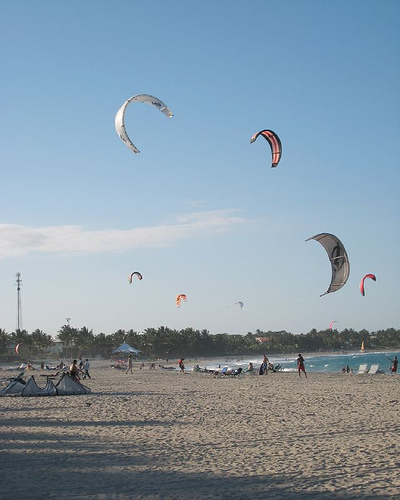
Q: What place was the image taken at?
A: It was taken at the beach.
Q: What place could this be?
A: It is a beach.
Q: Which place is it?
A: It is a beach.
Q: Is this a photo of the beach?
A: Yes, it is showing the beach.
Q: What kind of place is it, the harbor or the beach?
A: It is the beach.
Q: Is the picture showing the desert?
A: No, the picture is showing the beach.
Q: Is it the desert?
A: No, it is the beach.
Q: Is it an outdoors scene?
A: Yes, it is outdoors.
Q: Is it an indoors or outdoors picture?
A: It is outdoors.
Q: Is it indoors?
A: No, it is outdoors.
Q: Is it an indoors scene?
A: No, it is outdoors.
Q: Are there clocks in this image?
A: No, there are no clocks.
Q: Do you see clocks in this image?
A: No, there are no clocks.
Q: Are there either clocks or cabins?
A: No, there are no clocks or cabins.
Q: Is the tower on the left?
A: Yes, the tower is on the left of the image.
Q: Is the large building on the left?
A: Yes, the tower is on the left of the image.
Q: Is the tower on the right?
A: No, the tower is on the left of the image.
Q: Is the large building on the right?
A: No, the tower is on the left of the image.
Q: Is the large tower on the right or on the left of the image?
A: The tower is on the left of the image.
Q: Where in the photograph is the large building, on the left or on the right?
A: The tower is on the left of the image.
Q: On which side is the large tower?
A: The tower is on the left of the image.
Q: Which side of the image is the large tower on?
A: The tower is on the left of the image.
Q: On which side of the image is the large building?
A: The tower is on the left of the image.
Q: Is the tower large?
A: Yes, the tower is large.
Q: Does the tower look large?
A: Yes, the tower is large.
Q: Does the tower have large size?
A: Yes, the tower is large.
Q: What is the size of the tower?
A: The tower is large.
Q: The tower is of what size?
A: The tower is large.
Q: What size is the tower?
A: The tower is large.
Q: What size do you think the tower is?
A: The tower is large.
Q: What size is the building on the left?
A: The tower is large.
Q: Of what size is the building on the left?
A: The tower is large.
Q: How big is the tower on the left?
A: The tower is large.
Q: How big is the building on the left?
A: The tower is large.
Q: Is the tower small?
A: No, the tower is large.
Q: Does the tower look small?
A: No, the tower is large.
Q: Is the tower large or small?
A: The tower is large.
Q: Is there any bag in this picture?
A: No, there are no bags.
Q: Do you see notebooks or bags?
A: No, there are no bags or notebooks.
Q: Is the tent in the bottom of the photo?
A: Yes, the tent is in the bottom of the image.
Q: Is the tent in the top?
A: No, the tent is in the bottom of the image.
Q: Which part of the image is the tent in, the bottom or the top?
A: The tent is in the bottom of the image.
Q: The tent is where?
A: The tent is on the beach.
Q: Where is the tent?
A: The tent is on the beach.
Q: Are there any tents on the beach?
A: Yes, there is a tent on the beach.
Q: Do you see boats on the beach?
A: No, there is a tent on the beach.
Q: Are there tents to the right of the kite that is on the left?
A: Yes, there is a tent to the right of the kite.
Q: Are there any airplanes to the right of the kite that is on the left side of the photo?
A: No, there is a tent to the right of the kite.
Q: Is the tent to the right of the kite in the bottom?
A: Yes, the tent is to the right of the kite.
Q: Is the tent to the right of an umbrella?
A: No, the tent is to the right of the kite.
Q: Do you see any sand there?
A: Yes, there is sand.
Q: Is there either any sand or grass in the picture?
A: Yes, there is sand.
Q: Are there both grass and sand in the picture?
A: No, there is sand but no grass.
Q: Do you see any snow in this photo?
A: No, there is no snow.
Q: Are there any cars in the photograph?
A: No, there are no cars.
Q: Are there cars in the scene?
A: No, there are no cars.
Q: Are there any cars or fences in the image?
A: No, there are no cars or fences.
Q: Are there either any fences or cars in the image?
A: No, there are no cars or fences.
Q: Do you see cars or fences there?
A: No, there are no cars or fences.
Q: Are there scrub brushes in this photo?
A: No, there are no scrub brushes.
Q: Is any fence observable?
A: No, there are no fences.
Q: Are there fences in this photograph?
A: No, there are no fences.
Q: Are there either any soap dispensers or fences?
A: No, there are no fences or soap dispensers.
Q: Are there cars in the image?
A: No, there are no cars.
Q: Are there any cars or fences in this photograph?
A: No, there are no cars or fences.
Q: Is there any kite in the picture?
A: Yes, there is a kite.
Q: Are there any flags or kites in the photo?
A: Yes, there is a kite.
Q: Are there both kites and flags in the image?
A: No, there is a kite but no flags.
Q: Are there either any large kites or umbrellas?
A: Yes, there is a large kite.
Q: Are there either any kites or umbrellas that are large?
A: Yes, the kite is large.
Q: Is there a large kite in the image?
A: Yes, there is a large kite.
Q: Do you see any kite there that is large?
A: Yes, there is a kite that is large.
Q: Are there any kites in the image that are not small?
A: Yes, there is a large kite.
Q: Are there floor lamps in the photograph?
A: No, there are no floor lamps.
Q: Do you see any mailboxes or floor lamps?
A: No, there are no floor lamps or mailboxes.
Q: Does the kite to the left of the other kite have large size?
A: Yes, the kite is large.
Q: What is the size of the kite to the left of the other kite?
A: The kite is large.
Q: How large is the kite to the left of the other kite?
A: The kite is large.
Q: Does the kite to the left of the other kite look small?
A: No, the kite is large.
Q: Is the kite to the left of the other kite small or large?
A: The kite is large.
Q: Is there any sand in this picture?
A: Yes, there is sand.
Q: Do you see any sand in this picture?
A: Yes, there is sand.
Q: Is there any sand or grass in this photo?
A: Yes, there is sand.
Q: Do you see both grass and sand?
A: No, there is sand but no grass.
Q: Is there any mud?
A: No, there is no mud.